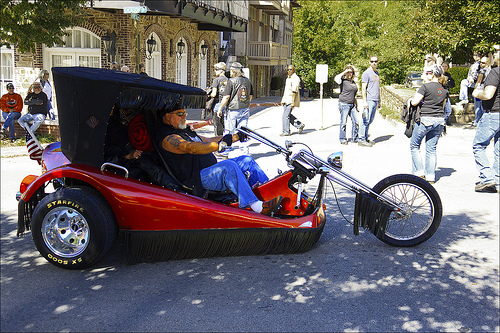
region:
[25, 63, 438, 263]
Red motercycle coup parked in crowd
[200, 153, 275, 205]
blue jeans worn by motorcycle driver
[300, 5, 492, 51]
Green trees behind the crowd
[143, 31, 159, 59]
street lamps on the building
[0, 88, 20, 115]
red shirt worn by man in the crowd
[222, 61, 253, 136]
man with motorcycle jacket in the background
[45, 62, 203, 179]
Black roof attached to motorcycle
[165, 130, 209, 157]
Tattoos on arm of man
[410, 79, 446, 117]
black shirt on lady in the crowd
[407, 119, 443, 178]
jeans worn by lady in the crowd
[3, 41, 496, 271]
driver attracting attention in red vehicle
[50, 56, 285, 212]
tattooed man under black hood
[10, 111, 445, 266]
front of motorcycle attached to cart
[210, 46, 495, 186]
people wearing jeans standing and walking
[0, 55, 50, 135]
people on and behind low brick wall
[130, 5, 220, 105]
black lanterns by arches in stone wall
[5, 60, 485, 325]
shade falling over vehicle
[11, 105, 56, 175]
small flag in back of cart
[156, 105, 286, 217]
driver with straight arm and bent knees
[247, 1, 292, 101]
wooden terraces on front of brown building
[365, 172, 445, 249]
Front wheel of bike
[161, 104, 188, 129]
A biker with glasses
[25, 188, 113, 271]
Rear wheel of bike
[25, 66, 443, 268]
Three wheeled bike with rider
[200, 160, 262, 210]
Mens blue denim pants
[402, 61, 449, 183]
Woman in black shirt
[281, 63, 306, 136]
Man in yellow shirt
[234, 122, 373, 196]
Steering column of bike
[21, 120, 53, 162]
A small US flag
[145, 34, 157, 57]
A decorative street lamp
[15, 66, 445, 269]
red and black customized chopper with fringe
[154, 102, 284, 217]
a man wearing a black shirt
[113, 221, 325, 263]
black fringe on bottom of chopper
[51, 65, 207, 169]
a black canopy roof with black fringe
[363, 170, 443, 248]
front wire spoked wheel on chopper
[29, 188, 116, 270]
a large black tire on back of chopper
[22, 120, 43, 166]
an American flag on back of chopper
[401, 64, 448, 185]
a woman wearing a black shirt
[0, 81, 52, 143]
two people sitting on a wall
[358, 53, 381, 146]
a man wearing black sunglasses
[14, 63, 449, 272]
Man riding 3 wheeled vehicle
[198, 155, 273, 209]
Man wearing blue jeans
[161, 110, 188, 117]
Man wearing sunglasses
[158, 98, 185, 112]
Man wearing skull cap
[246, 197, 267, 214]
Man wearing white socks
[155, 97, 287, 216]
Man is sitting down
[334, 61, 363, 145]
Woman shielding her eyes from sun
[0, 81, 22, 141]
Woman is sitting down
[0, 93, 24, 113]
Woman wearing red shirt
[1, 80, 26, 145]
Woman with her legs crossed